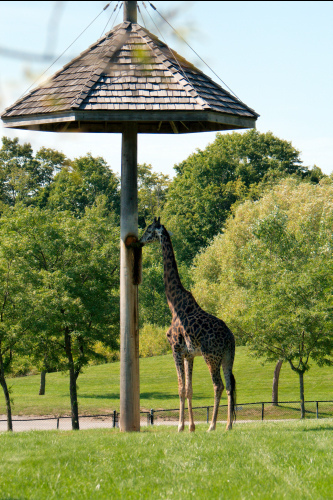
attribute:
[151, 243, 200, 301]
neck of giraffe — large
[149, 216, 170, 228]
ears of giraffe — small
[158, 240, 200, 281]
trunk of giraffe — little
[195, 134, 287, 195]
green trees — big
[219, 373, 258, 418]
hairy tail — large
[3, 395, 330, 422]
coated metal fencing — green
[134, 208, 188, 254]
head of the zebra — Tall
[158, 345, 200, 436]
two front legs — Brown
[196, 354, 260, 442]
two back legs — Brown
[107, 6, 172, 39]
shingle on a roof — Brown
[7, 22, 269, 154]
roof — Brown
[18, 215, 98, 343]
trees with branches — Green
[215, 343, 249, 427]
tail with fringes — Long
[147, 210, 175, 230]
knobbed horn — Short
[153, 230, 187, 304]
neck of the giraffe — Long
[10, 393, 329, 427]
fencing near — Thin